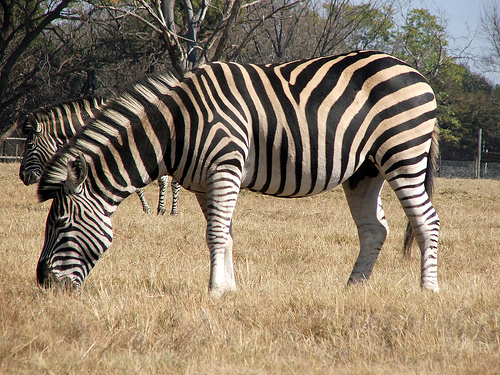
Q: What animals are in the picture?
A: Zebras.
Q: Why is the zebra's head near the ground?
A: It is eating.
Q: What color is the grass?
A: Brown.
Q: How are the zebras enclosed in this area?
A: A fence.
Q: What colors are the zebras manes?
A: Black and white.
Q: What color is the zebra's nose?
A: Black.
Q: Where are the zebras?
A: The zebras are in a field.